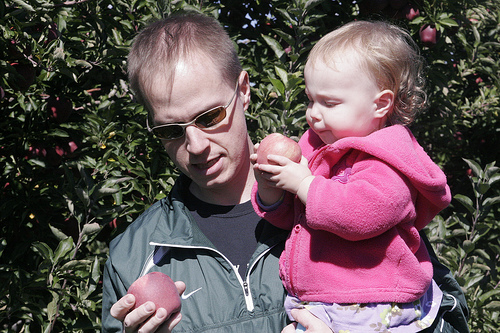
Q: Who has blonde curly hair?
A: The toddler.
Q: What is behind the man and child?
A: Apple tree.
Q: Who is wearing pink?
A: The toddler.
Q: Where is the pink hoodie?
A: On the toddler.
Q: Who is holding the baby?
A: The man with glasses.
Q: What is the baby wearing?
A: A hoodie.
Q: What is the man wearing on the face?
A: Sunglasses.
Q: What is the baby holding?
A: An apple.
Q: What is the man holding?
A: An apple.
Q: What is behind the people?
A: An apple bush.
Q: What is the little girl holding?
A: An apple.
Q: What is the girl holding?
A: An apple.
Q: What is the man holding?
A: An apple and a baby.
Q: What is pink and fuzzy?
A: The jacket of the baby.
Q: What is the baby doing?
A: Holding an apple.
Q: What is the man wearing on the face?
A: Sunglasses.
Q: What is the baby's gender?
A: Female.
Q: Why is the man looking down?
A: The apple is there.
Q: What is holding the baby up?
A: The man.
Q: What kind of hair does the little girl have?
A: Curly.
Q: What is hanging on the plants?
A: Apples.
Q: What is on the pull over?
A: Zipper.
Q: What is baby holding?
A: Apple.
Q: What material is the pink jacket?
A: Fuzzy.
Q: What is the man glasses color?
A: Brown.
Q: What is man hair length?
A: Short.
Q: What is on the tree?
A: Leaves.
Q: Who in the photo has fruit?
A: Everybody.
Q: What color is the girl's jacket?
A: Pink.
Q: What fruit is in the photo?
A: Apple.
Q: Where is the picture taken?
A: Apple orchid.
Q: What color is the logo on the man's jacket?
A: White.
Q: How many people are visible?
A: 2.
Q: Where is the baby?
A: In the man's arm.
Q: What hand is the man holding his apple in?
A: Right.